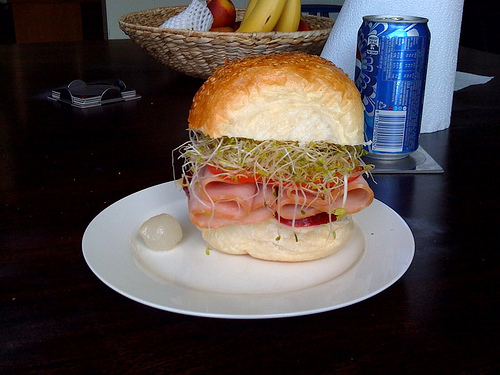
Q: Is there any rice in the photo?
A: No, there is no rice.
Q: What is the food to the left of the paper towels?
A: The food is a bun.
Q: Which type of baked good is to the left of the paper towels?
A: The food is a bun.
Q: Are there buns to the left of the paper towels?
A: Yes, there is a bun to the left of the paper towels.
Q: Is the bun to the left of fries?
A: No, the bun is to the left of the paper towels.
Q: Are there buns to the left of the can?
A: Yes, there is a bun to the left of the can.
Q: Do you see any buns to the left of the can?
A: Yes, there is a bun to the left of the can.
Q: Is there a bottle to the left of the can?
A: No, there is a bun to the left of the can.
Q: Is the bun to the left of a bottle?
A: No, the bun is to the left of a can.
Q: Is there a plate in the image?
A: Yes, there is a plate.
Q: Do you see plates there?
A: Yes, there is a plate.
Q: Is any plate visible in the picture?
A: Yes, there is a plate.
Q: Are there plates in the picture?
A: Yes, there is a plate.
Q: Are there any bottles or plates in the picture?
A: Yes, there is a plate.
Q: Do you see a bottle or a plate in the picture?
A: Yes, there is a plate.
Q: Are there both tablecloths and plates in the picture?
A: No, there is a plate but no tablecloths.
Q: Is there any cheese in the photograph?
A: No, there is no cheese.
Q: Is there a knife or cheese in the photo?
A: No, there are no cheese or knives.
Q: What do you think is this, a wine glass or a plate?
A: This is a plate.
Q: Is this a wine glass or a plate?
A: This is a plate.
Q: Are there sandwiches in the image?
A: Yes, there is a sandwich.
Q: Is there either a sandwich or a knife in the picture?
A: Yes, there is a sandwich.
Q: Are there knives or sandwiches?
A: Yes, there is a sandwich.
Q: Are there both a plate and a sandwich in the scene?
A: Yes, there are both a sandwich and a plate.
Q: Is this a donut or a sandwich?
A: This is a sandwich.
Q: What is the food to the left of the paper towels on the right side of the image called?
A: The food is a sandwich.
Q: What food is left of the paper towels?
A: The food is a sandwich.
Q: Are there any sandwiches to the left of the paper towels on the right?
A: Yes, there is a sandwich to the left of the paper towels.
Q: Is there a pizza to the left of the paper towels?
A: No, there is a sandwich to the left of the paper towels.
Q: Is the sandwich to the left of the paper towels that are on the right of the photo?
A: Yes, the sandwich is to the left of the paper towels.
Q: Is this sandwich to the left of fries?
A: No, the sandwich is to the left of the paper towels.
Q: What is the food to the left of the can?
A: The food is a sandwich.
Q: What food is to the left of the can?
A: The food is a sandwich.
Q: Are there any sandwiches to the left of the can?
A: Yes, there is a sandwich to the left of the can.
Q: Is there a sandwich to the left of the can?
A: Yes, there is a sandwich to the left of the can.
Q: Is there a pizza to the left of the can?
A: No, there is a sandwich to the left of the can.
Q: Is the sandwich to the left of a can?
A: Yes, the sandwich is to the left of a can.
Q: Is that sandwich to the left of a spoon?
A: No, the sandwich is to the left of a can.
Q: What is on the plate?
A: The sandwich is on the plate.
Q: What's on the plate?
A: The sandwich is on the plate.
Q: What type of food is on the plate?
A: The food is a sandwich.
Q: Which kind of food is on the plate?
A: The food is a sandwich.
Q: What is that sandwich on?
A: The sandwich is on the plate.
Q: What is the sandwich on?
A: The sandwich is on the plate.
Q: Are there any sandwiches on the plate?
A: Yes, there is a sandwich on the plate.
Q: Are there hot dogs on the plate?
A: No, there is a sandwich on the plate.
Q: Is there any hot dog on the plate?
A: No, there is a sandwich on the plate.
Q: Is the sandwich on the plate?
A: Yes, the sandwich is on the plate.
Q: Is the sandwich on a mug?
A: No, the sandwich is on the plate.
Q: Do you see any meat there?
A: Yes, there is meat.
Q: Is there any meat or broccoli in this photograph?
A: Yes, there is meat.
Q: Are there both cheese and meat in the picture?
A: No, there is meat but no cheese.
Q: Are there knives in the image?
A: No, there are no knives.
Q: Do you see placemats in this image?
A: No, there are no placemats.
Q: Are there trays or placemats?
A: No, there are no placemats or trays.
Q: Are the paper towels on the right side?
A: Yes, the paper towels are on the right of the image.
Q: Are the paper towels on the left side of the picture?
A: No, the paper towels are on the right of the image.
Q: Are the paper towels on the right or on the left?
A: The paper towels are on the right of the image.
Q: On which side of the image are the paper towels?
A: The paper towels are on the right of the image.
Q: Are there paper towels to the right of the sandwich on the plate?
A: Yes, there are paper towels to the right of the sandwich.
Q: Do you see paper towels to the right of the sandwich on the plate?
A: Yes, there are paper towels to the right of the sandwich.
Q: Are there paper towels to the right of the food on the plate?
A: Yes, there are paper towels to the right of the sandwich.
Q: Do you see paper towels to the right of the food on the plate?
A: Yes, there are paper towels to the right of the sandwich.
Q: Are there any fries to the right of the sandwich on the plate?
A: No, there are paper towels to the right of the sandwich.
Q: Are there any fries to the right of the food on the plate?
A: No, there are paper towels to the right of the sandwich.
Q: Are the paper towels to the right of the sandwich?
A: Yes, the paper towels are to the right of the sandwich.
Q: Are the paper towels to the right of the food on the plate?
A: Yes, the paper towels are to the right of the sandwich.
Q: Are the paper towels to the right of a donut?
A: No, the paper towels are to the right of the sandwich.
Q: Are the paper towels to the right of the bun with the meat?
A: Yes, the paper towels are to the right of the bun.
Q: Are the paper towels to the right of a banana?
A: Yes, the paper towels are to the right of a banana.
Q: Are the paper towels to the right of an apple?
A: No, the paper towels are to the right of a banana.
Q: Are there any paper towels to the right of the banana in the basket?
A: Yes, there are paper towels to the right of the banana.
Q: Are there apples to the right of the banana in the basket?
A: No, there are paper towels to the right of the banana.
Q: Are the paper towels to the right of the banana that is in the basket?
A: Yes, the paper towels are to the right of the banana.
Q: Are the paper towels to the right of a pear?
A: No, the paper towels are to the right of the banana.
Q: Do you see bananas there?
A: Yes, there is a banana.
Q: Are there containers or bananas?
A: Yes, there is a banana.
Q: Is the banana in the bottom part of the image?
A: No, the banana is in the top of the image.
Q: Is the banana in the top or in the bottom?
A: The banana is in the top of the image.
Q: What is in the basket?
A: The banana is in the basket.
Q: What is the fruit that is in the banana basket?
A: The fruit is a banana.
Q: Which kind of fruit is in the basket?
A: The fruit is a banana.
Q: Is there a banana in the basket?
A: Yes, there is a banana in the basket.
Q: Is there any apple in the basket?
A: No, there is a banana in the basket.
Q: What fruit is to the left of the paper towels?
A: The fruit is a banana.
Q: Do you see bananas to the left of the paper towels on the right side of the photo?
A: Yes, there is a banana to the left of the paper towels.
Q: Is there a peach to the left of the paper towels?
A: No, there is a banana to the left of the paper towels.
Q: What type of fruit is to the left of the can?
A: The fruit is a banana.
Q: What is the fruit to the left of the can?
A: The fruit is a banana.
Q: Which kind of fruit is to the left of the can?
A: The fruit is a banana.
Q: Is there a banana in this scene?
A: Yes, there is a banana.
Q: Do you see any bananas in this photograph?
A: Yes, there is a banana.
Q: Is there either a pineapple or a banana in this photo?
A: Yes, there is a banana.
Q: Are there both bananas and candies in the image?
A: No, there is a banana but no candies.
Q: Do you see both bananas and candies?
A: No, there is a banana but no candies.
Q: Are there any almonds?
A: No, there are no almonds.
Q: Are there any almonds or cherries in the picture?
A: No, there are no almonds or cherries.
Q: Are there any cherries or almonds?
A: No, there are no almonds or cherries.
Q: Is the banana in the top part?
A: Yes, the banana is in the top of the image.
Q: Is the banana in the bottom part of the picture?
A: No, the banana is in the top of the image.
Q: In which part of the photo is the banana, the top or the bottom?
A: The banana is in the top of the image.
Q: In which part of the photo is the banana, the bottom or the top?
A: The banana is in the top of the image.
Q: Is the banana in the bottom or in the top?
A: The banana is in the top of the image.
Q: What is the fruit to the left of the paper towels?
A: The fruit is a banana.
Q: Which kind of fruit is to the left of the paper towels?
A: The fruit is a banana.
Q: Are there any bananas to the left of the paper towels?
A: Yes, there is a banana to the left of the paper towels.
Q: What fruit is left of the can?
A: The fruit is a banana.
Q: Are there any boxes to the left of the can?
A: No, there is a banana to the left of the can.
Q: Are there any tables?
A: Yes, there is a table.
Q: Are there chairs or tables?
A: Yes, there is a table.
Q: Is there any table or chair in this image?
A: Yes, there is a table.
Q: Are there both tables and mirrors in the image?
A: No, there is a table but no mirrors.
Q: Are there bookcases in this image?
A: No, there are no bookcases.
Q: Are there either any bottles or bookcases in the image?
A: No, there are no bookcases or bottles.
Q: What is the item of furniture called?
A: The piece of furniture is a table.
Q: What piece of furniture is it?
A: The piece of furniture is a table.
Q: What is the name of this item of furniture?
A: This is a table.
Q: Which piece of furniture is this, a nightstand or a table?
A: This is a table.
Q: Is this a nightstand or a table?
A: This is a table.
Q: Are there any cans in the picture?
A: Yes, there is a can.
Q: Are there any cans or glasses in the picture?
A: Yes, there is a can.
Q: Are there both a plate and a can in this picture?
A: Yes, there are both a can and a plate.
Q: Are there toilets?
A: No, there are no toilets.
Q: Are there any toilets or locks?
A: No, there are no toilets or locks.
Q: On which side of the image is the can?
A: The can is on the right of the image.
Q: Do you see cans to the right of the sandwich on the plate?
A: Yes, there is a can to the right of the sandwich.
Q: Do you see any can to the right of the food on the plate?
A: Yes, there is a can to the right of the sandwich.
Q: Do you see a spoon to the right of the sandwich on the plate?
A: No, there is a can to the right of the sandwich.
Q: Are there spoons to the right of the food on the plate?
A: No, there is a can to the right of the sandwich.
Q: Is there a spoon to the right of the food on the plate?
A: No, there is a can to the right of the sandwich.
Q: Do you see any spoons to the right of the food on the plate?
A: No, there is a can to the right of the sandwich.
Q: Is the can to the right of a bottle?
A: No, the can is to the right of the sandwich.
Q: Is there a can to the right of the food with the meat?
A: Yes, there is a can to the right of the bun.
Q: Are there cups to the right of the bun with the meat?
A: No, there is a can to the right of the bun.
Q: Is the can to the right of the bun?
A: Yes, the can is to the right of the bun.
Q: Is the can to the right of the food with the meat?
A: Yes, the can is to the right of the bun.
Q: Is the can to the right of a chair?
A: No, the can is to the right of the bun.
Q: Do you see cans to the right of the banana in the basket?
A: Yes, there is a can to the right of the banana.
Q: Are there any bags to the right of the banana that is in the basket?
A: No, there is a can to the right of the banana.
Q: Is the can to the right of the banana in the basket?
A: Yes, the can is to the right of the banana.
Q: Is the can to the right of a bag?
A: No, the can is to the right of the banana.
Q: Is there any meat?
A: Yes, there is meat.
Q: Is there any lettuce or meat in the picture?
A: Yes, there is meat.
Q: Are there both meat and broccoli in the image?
A: No, there is meat but no broccoli.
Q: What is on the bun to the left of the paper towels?
A: The meat is on the bun.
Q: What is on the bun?
A: The meat is on the bun.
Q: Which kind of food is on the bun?
A: The food is meat.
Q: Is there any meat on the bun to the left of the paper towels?
A: Yes, there is meat on the bun.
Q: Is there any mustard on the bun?
A: No, there is meat on the bun.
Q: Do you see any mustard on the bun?
A: No, there is meat on the bun.